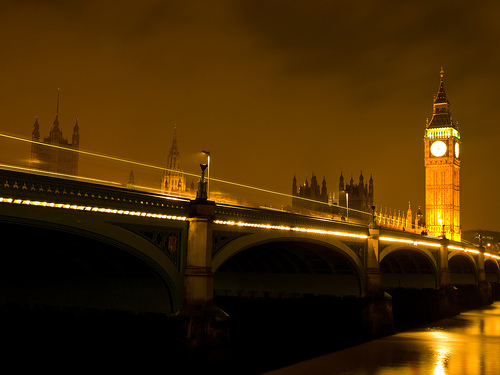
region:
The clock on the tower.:
[399, 123, 472, 184]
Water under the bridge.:
[286, 322, 488, 364]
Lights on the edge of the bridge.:
[74, 193, 366, 241]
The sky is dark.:
[126, 55, 379, 158]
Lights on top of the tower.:
[416, 122, 461, 140]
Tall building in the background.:
[148, 130, 208, 198]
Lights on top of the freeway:
[35, 133, 332, 214]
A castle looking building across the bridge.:
[291, 165, 389, 221]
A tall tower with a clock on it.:
[416, 71, 467, 238]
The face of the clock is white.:
[431, 133, 446, 158]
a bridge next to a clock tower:
[23, 44, 490, 319]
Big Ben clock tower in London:
[418, 56, 471, 265]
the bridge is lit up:
[20, 120, 430, 260]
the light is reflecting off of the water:
[363, 298, 499, 373]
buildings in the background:
[276, 158, 381, 225]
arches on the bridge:
[5, 201, 485, 352]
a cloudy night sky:
[38, 18, 420, 134]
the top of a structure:
[148, 128, 198, 198]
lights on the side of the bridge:
[5, 187, 190, 225]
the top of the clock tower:
[425, 59, 463, 126]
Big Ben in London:
[405, 54, 487, 259]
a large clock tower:
[408, 45, 497, 279]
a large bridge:
[12, 143, 499, 301]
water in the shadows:
[103, 309, 467, 356]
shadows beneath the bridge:
[228, 264, 373, 323]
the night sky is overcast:
[12, 10, 468, 135]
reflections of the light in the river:
[391, 311, 493, 366]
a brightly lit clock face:
[415, 135, 450, 156]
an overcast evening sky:
[16, 8, 416, 128]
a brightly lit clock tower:
[413, 53, 473, 236]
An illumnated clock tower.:
[420, 63, 464, 245]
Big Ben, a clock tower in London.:
[419, 63, 466, 243]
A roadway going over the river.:
[1, 135, 498, 295]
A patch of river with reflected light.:
[397, 325, 494, 374]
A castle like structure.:
[289, 168, 377, 222]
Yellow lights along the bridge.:
[2, 189, 499, 264]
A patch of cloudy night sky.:
[104, 18, 386, 125]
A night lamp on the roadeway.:
[200, 147, 215, 199]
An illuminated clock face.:
[430, 140, 447, 155]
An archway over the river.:
[208, 222, 365, 312]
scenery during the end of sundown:
[0, 5, 499, 372]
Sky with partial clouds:
[0, 7, 427, 115]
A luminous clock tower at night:
[421, 62, 462, 239]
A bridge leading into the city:
[1, 217, 496, 264]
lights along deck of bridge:
[307, 225, 367, 235]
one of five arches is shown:
[214, 230, 363, 320]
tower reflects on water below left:
[391, 300, 498, 372]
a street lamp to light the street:
[196, 146, 217, 163]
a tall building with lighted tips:
[26, 86, 86, 171]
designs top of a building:
[286, 168, 380, 205]